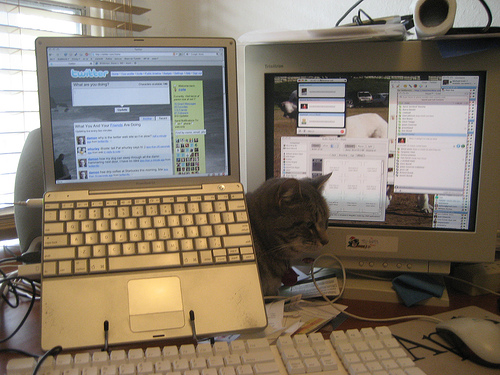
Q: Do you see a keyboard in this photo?
A: Yes, there is a keyboard.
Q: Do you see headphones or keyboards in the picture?
A: Yes, there is a keyboard.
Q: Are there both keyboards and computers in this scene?
A: Yes, there are both a keyboard and a computer.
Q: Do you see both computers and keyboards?
A: Yes, there are both a keyboard and a computer.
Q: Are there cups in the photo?
A: No, there are no cups.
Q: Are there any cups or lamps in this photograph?
A: No, there are no cups or lamps.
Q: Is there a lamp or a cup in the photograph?
A: No, there are no cups or lamps.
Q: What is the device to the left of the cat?
A: The device is a keyboard.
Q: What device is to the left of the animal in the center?
A: The device is a keyboard.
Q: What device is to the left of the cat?
A: The device is a keyboard.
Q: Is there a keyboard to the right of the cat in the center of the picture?
A: No, the keyboard is to the left of the cat.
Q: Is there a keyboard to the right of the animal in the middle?
A: No, the keyboard is to the left of the cat.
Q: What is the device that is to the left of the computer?
A: The device is a keyboard.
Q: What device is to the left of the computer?
A: The device is a keyboard.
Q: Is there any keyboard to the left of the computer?
A: Yes, there is a keyboard to the left of the computer.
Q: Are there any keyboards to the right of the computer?
A: No, the keyboard is to the left of the computer.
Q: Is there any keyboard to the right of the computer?
A: No, the keyboard is to the left of the computer.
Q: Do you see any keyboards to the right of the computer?
A: No, the keyboard is to the left of the computer.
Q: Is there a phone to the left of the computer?
A: No, there is a keyboard to the left of the computer.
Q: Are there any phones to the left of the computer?
A: No, there is a keyboard to the left of the computer.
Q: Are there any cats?
A: Yes, there is a cat.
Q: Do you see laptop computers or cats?
A: Yes, there is a cat.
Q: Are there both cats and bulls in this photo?
A: No, there is a cat but no bulls.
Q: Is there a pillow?
A: No, there are no pillows.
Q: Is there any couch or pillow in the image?
A: No, there are no pillows or couches.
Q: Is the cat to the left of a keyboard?
A: No, the cat is to the right of a keyboard.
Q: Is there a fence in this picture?
A: No, there are no fences.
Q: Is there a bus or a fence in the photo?
A: No, there are no fences or buses.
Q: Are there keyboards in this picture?
A: Yes, there is a keyboard.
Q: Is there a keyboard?
A: Yes, there is a keyboard.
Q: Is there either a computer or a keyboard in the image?
A: Yes, there is a keyboard.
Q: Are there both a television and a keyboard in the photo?
A: No, there is a keyboard but no televisions.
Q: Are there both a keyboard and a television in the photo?
A: No, there is a keyboard but no televisions.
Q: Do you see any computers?
A: Yes, there is a computer.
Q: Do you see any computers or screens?
A: Yes, there is a computer.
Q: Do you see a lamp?
A: No, there are no lamps.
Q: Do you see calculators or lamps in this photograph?
A: No, there are no lamps or calculators.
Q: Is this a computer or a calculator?
A: This is a computer.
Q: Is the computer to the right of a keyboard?
A: Yes, the computer is to the right of a keyboard.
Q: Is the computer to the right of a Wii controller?
A: No, the computer is to the right of a keyboard.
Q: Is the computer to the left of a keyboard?
A: No, the computer is to the right of a keyboard.